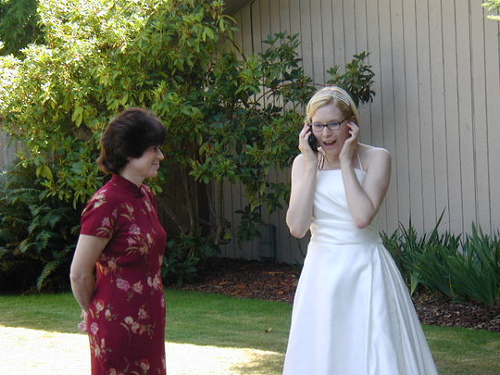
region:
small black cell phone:
[289, 119, 322, 152]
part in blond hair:
[324, 83, 352, 118]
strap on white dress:
[355, 136, 367, 173]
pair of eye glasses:
[300, 111, 356, 133]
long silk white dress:
[294, 251, 409, 332]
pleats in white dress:
[379, 248, 410, 343]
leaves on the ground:
[205, 267, 289, 298]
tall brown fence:
[396, 73, 476, 217]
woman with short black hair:
[70, 106, 177, 173]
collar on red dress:
[112, 170, 162, 211]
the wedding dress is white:
[301, 160, 416, 372]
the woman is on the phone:
[288, 94, 423, 373]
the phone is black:
[296, 108, 329, 153]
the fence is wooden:
[393, 45, 485, 168]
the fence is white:
[406, 40, 465, 160]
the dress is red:
[80, 175, 192, 372]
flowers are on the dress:
[91, 190, 176, 366]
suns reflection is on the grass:
[33, 316, 98, 371]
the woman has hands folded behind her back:
[77, 113, 217, 373]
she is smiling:
[286, 80, 415, 374]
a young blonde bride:
[270, 61, 472, 373]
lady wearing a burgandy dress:
[62, 77, 197, 370]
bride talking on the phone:
[243, 43, 418, 363]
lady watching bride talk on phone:
[66, 44, 395, 349]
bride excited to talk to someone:
[256, 38, 421, 285]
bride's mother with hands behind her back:
[52, 85, 201, 357]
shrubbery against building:
[16, 6, 497, 319]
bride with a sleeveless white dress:
[270, 79, 403, 298]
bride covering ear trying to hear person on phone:
[280, 64, 417, 250]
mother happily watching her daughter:
[51, 35, 415, 326]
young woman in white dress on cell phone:
[285, 88, 438, 374]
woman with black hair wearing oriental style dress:
[69, 107, 171, 374]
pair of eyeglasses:
[309, 118, 344, 129]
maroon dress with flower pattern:
[69, 176, 168, 374]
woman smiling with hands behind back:
[70, 106, 170, 372]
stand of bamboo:
[2, 0, 287, 288]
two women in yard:
[65, 85, 436, 371]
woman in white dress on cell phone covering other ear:
[283, 87, 430, 372]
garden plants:
[376, 213, 496, 333]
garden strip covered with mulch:
[165, 257, 497, 329]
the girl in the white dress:
[286, 80, 439, 365]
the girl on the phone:
[273, 70, 443, 371]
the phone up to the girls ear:
[302, 121, 322, 153]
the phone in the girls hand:
[293, 121, 320, 165]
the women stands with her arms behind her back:
[53, 90, 184, 372]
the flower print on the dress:
[84, 270, 167, 373]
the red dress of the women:
[89, 169, 176, 370]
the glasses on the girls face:
[304, 111, 351, 136]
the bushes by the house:
[2, 144, 77, 289]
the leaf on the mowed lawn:
[254, 320, 279, 339]